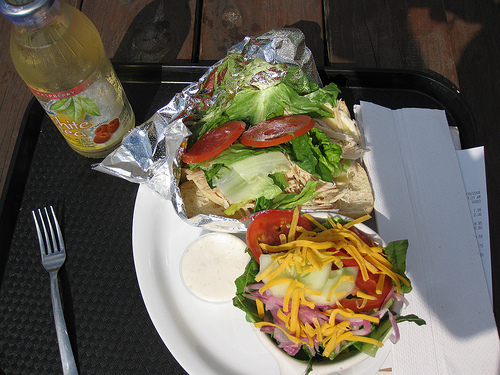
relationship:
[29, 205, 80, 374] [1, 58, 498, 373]
fork on black tray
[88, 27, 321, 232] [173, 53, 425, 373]
foil containing food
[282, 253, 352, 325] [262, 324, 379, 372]
salad in bowl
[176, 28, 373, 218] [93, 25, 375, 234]
sandwich in foil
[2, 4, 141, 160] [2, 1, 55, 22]
bottle gas cap